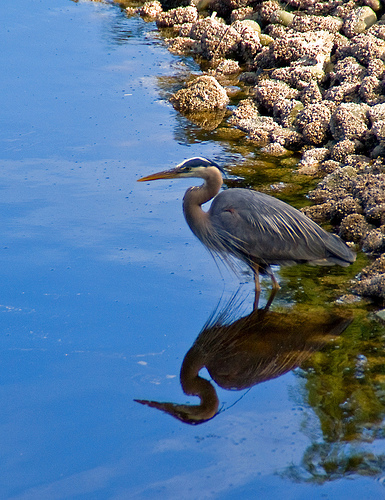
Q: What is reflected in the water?
A: The animal.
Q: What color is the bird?
A: Gray and white.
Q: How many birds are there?
A: One.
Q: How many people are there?
A: None.